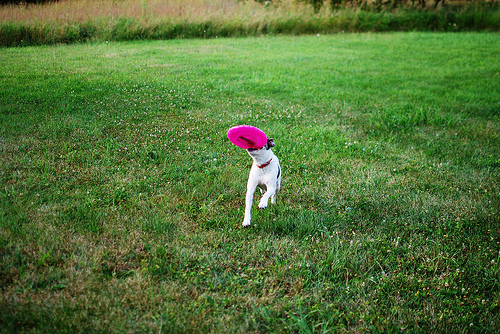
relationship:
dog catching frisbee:
[241, 124, 282, 228] [224, 123, 266, 149]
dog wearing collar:
[241, 124, 282, 228] [248, 156, 275, 168]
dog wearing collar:
[241, 124, 282, 228] [249, 153, 279, 174]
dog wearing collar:
[241, 124, 282, 228] [253, 153, 276, 171]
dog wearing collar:
[241, 124, 282, 228] [255, 157, 270, 168]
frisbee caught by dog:
[226, 125, 266, 150] [195, 93, 313, 251]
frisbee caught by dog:
[224, 120, 271, 154] [241, 124, 282, 228]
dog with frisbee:
[241, 124, 282, 228] [222, 120, 267, 152]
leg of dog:
[239, 178, 256, 230] [221, 125, 281, 228]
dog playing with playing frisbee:
[241, 124, 282, 228] [225, 118, 288, 208]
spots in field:
[101, 43, 217, 68] [105, 36, 250, 83]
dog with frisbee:
[241, 124, 282, 228] [225, 125, 267, 148]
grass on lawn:
[1, 25, 497, 330] [2, 28, 476, 329]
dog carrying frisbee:
[241, 124, 282, 228] [224, 121, 266, 151]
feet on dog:
[238, 172, 286, 232] [212, 114, 289, 234]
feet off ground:
[238, 172, 286, 232] [218, 200, 299, 244]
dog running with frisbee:
[241, 124, 282, 228] [226, 123, 269, 151]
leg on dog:
[239, 178, 256, 230] [241, 124, 282, 228]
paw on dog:
[238, 213, 258, 231] [235, 110, 302, 245]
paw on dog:
[256, 195, 271, 213] [208, 107, 308, 244]